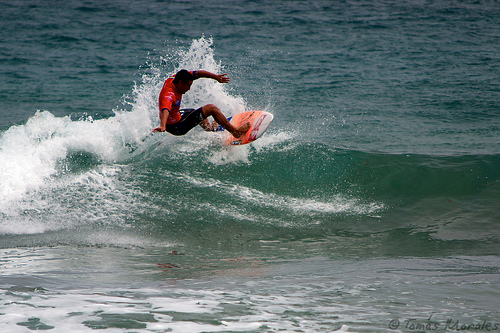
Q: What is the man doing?
A: Surfing.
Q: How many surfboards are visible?
A: 1.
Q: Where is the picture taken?
A: The ocean.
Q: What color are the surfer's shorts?
A: Black.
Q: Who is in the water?
A: Surfer.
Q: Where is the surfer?
A: On a wave.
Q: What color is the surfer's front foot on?
A: Orange.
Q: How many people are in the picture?
A: 1.